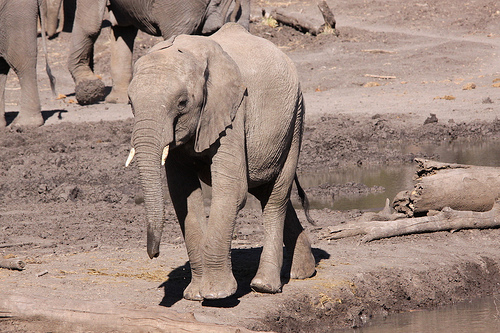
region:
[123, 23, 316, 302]
An elephant walking on dirt.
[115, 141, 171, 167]
Elephant has white tusks.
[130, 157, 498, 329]
Water standing in two dirt holes.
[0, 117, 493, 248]
Loose dirt on the ground.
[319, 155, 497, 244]
Wooden logs on the ground.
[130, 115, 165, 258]
Ridges on the elephant's trunk.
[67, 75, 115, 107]
Mud on an elephant's hoof.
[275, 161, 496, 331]
Small ripples the water's surface.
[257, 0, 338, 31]
A wooden log lying in the dirt.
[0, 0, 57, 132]
Tail end of an elephant.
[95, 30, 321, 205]
gray elephant on the ground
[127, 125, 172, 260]
trunk of the elephant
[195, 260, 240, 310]
foot of the elephant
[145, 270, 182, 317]
shadow on the ground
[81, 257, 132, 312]
dirt on the ground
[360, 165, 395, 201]
water behind the elephant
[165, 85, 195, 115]
eye of the elephant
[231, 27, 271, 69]
back of the elephant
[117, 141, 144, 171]
tusk of the elephant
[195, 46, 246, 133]
ear of the elephant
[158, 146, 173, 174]
white tusk on the elephant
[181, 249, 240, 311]
legs of the elephant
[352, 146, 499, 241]
log on the ground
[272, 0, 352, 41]
rock on the ground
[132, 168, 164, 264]
trunk of the elephant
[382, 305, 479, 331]
muddy water in the watering hole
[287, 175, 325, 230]
tail of the elephant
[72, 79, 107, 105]
nose of the elephant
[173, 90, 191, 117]
eye of the elephant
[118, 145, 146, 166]
small tusk on elephant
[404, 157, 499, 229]
wood on the ground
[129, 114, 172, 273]
baby elephant trunk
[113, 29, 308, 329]
a small elephant walking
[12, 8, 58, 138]
a large elephant leg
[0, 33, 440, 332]
elephant walking next to water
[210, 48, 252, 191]
a baby elephant ear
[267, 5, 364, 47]
a rock inthe background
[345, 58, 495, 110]
orange in the dirt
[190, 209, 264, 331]
elephant shadow on ground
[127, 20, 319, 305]
Small elephant is walking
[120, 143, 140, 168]
Small ivory tusk on elephant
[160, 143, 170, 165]
Small ivory tusk on elephant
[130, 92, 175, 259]
Trunk is slightly wet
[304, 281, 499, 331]
Water next to elephant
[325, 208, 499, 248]
Tree trunk behind elephant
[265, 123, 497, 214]
Mud behind small elephant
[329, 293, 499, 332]
Water is brown and murky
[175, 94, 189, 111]
Eye on small elephant is opened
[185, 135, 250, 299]
Leg of elephant is lifted off ground